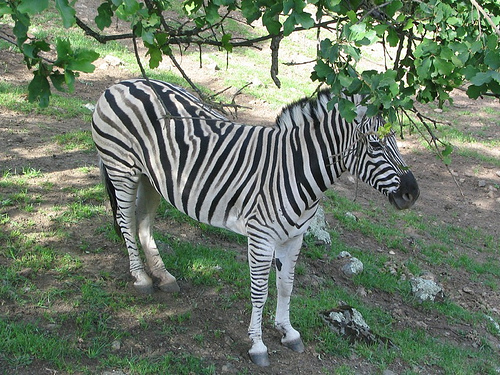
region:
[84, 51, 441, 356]
zebra standing under a tree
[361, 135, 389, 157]
eye on the zebra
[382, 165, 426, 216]
nose on the zebra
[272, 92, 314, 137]
mane on the zebra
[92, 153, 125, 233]
tale on the zebra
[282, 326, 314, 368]
hoof on the zebra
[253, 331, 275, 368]
hoof on the zebra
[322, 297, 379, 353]
rock on the ground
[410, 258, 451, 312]
rock on the ground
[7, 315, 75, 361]
grass on the ground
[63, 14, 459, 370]
a zebra at a zoo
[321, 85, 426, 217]
the head of a zebra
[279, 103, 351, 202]
the neck of a zebra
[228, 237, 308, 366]
the front legs of a zebra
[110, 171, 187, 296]
the rear legs of a zebra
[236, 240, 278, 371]
the front leg of a zebra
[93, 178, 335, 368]
the legs of a zebra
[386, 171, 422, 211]
the nose of a zebra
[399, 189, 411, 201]
the nostril of a zebra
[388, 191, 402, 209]
the mouth of a zebra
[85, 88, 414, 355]
Zebra standing under tree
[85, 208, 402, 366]
Grass and dirt below zebra's feet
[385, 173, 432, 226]
Black nose and mouth of zebra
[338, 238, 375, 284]
Small rocks in grassy area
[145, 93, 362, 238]
White and black stripes on zebra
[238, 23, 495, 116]
Green leaves on branches above zebra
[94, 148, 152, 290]
Black tail hanging on zebra's rear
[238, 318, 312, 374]
Zebra's hoofs digging into dirt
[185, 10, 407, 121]
Sunshine coming down on grass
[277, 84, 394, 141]
Stiff mane of zebra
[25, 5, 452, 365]
zebra standing in the shade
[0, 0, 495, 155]
green leaves of a tree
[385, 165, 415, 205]
black nose of zebra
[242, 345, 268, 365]
front right hoof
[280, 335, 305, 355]
left front hoof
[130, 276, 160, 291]
back right hoof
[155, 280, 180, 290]
back left hoof of zebra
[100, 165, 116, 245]
black tail of zebra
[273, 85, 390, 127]
spikey mane of zebra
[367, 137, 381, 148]
eye of the zebra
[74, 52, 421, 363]
The zebra standing under the tree.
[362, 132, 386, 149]
The eye of the zebra.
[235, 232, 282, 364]
The left front leg of the zebra.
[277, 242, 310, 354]
The right front leg of the zebra.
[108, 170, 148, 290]
The back left leg.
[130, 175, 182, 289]
The back right leg.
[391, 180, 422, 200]
The nose of the zebra.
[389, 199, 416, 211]
The mouth of the zebra.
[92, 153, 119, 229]
The tail of the zebra.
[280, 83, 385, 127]
The mane on the back of the zebra.